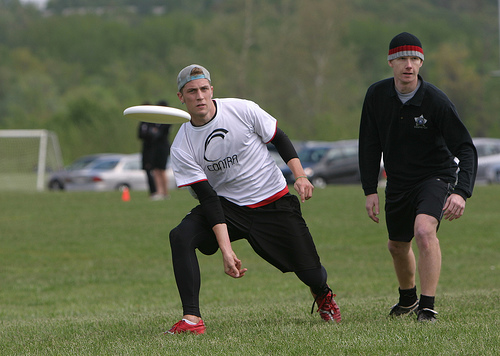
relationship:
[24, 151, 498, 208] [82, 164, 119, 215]
these are parked vehicles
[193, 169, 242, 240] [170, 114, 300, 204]
sleeve on shirt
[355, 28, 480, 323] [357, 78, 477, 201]
man wearing shirt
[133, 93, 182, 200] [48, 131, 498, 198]
people standing near vehicles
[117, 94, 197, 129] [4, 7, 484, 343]
disk in the air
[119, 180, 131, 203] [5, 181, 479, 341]
cone on the field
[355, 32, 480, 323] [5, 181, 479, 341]
man on a field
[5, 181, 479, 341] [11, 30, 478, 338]
field in a park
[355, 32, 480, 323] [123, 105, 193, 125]
man playing disk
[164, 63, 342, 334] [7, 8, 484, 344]
man at the park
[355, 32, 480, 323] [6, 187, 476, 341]
man standing on the ground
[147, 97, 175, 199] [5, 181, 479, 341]
people standing in a field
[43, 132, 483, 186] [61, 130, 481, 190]
cars parked in a lot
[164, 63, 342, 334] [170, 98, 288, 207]
man in a shirt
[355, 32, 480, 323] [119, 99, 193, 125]
man playing frisbee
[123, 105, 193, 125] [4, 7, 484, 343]
disk flying through the air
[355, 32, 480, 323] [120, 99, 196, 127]
man near a frisbee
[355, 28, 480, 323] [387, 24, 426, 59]
man wearing a cap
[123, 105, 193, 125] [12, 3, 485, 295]
disk in air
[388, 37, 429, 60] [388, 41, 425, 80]
cap in head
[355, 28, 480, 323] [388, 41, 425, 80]
man has head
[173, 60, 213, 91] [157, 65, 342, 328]
hat on head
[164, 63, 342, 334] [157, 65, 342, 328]
man has head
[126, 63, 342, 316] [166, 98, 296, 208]
man wearing shirt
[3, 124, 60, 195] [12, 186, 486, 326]
net in field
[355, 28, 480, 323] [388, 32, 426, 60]
man wearing cap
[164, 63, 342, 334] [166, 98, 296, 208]
man wearing shirt